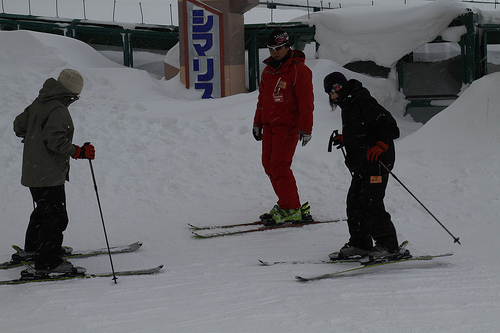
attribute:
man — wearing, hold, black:
[227, 13, 332, 183]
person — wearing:
[241, 21, 325, 168]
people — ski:
[2, 19, 427, 283]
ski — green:
[155, 128, 220, 174]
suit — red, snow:
[238, 66, 332, 200]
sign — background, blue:
[174, 15, 252, 109]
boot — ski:
[262, 196, 321, 235]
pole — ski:
[374, 165, 467, 261]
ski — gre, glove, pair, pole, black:
[68, 222, 163, 296]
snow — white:
[156, 168, 197, 217]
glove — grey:
[236, 134, 318, 151]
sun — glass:
[267, 40, 287, 55]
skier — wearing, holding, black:
[9, 50, 137, 272]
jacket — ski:
[10, 102, 113, 202]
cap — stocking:
[320, 71, 348, 93]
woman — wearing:
[267, 64, 392, 263]